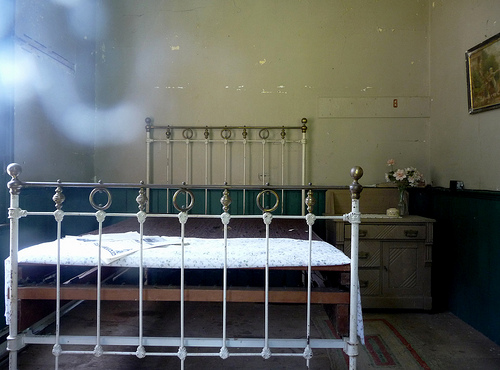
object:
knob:
[350, 165, 362, 179]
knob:
[7, 162, 20, 176]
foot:
[5, 162, 366, 370]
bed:
[6, 119, 361, 369]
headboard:
[142, 116, 309, 216]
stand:
[16, 282, 349, 335]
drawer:
[343, 223, 428, 241]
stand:
[326, 184, 437, 311]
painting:
[465, 31, 499, 114]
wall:
[426, 3, 498, 344]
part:
[429, 313, 498, 370]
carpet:
[0, 300, 499, 369]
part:
[308, 291, 351, 304]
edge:
[355, 276, 366, 346]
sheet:
[4, 231, 364, 348]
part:
[315, 212, 342, 224]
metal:
[17, 211, 353, 223]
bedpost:
[347, 165, 365, 369]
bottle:
[396, 188, 410, 217]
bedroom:
[0, 1, 498, 369]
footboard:
[4, 163, 368, 369]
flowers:
[392, 169, 407, 182]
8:
[392, 99, 397, 108]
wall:
[1, 3, 431, 303]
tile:
[403, 97, 431, 118]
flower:
[385, 158, 396, 166]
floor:
[1, 288, 494, 370]